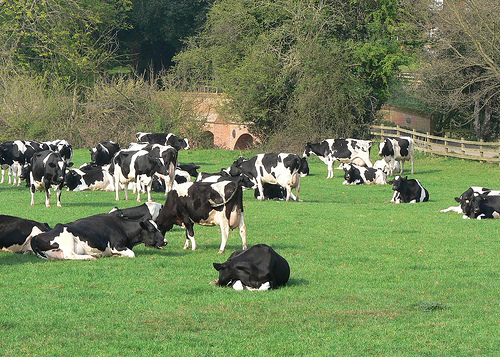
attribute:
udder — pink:
[284, 171, 301, 189]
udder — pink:
[348, 152, 368, 167]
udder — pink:
[138, 167, 152, 188]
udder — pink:
[212, 207, 242, 229]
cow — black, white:
[215, 239, 293, 290]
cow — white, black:
[144, 176, 245, 242]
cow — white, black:
[445, 178, 499, 216]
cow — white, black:
[387, 173, 432, 206]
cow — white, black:
[374, 132, 415, 172]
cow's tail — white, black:
[223, 190, 238, 207]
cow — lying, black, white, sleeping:
[209, 241, 291, 293]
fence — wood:
[368, 123, 498, 163]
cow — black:
[169, 223, 324, 305]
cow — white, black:
[196, 239, 300, 309]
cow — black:
[154, 178, 247, 252]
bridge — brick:
[131, 87, 442, 148]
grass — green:
[5, 142, 499, 350]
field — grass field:
[2, 140, 498, 344]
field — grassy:
[48, 92, 463, 310]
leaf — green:
[384, 51, 396, 65]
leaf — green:
[395, 21, 410, 33]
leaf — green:
[345, 34, 356, 49]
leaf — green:
[255, 80, 267, 92]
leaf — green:
[248, 15, 260, 27]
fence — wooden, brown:
[367, 118, 499, 172]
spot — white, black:
[266, 169, 284, 184]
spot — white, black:
[254, 163, 267, 175]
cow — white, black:
[152, 170, 250, 257]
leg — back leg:
[234, 214, 250, 252]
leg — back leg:
[212, 218, 233, 256]